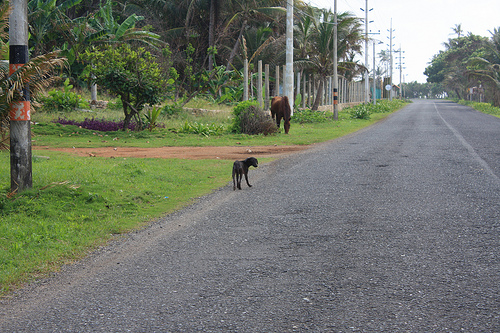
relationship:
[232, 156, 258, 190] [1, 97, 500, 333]
animal in main road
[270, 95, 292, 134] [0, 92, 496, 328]
animal by side of road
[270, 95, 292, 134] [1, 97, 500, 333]
animal by main road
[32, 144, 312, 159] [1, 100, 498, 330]
dirt driveway on main road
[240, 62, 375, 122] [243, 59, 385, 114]
poles on fence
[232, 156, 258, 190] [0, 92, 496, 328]
animal on road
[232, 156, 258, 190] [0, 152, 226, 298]
animal on green grass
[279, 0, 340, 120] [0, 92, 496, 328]
poles near road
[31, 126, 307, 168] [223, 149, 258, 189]
dirt road behind dog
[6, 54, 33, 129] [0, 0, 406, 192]
sign on power poles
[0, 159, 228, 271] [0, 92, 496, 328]
green grass by road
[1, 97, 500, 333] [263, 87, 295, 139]
main road by animal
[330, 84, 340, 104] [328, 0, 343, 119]
sign on pole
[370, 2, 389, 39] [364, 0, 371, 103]
wire on telephone pole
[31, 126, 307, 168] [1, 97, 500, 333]
dirt road to main road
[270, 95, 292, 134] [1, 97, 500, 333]
animal near main road